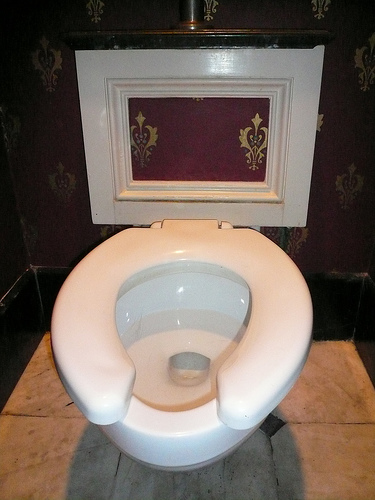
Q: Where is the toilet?
A: By the wall.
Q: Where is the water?
A: In the toilet.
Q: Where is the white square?
A: Above the toilet.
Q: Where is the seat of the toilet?
A: Above the water.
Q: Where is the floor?
A: Below the toilet.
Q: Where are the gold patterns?
A: On the wall.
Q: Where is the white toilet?
A: On the wall.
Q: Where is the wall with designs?
A: Behind the toilet.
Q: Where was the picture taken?
A: In a bathroom.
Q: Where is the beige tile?
A: On the floor.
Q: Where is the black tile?
A: Bottom of the wall.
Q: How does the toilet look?
A: Clean.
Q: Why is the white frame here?
A: That's a mystery.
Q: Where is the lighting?
A: Directly overhead.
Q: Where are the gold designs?
A: On the wall.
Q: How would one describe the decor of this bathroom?
A: Dark red wallpaper with a decorative golden design.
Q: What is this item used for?
A: Relieving oneself.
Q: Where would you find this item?
A: In a restroom.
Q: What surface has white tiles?
A: The floor.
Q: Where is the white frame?
A: On the toilet tank.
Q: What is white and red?
A: The wallpaper.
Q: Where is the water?
A: In the toilet.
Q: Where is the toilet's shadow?
A: On the floor.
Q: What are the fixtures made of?
A: Metal.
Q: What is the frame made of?
A: Wood.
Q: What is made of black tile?
A: The baseboard.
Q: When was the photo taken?
A: Night time.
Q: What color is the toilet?
A: White.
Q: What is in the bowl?
A: Water.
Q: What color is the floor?
A: Brown.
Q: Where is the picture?
A: On the wall.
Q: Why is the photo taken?
A: To show the toilet.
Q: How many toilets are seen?
A: One.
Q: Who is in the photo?
A: No one.